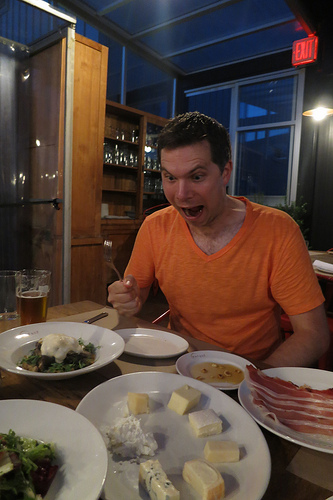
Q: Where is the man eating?
A: Restaurant.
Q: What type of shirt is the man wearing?
A: Tee.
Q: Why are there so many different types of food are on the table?
A: Variety.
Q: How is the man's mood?
A: Excited.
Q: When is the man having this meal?
A: In the evening.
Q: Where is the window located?
A: Behind the man.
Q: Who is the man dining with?
A: A friend.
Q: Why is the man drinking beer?
A: He likes it.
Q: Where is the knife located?
A: On table to the left of man.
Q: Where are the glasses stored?
A: On shelves in the rear left of the man.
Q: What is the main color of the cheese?
A: White.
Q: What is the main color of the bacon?
A: Red.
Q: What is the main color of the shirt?
A: Orange.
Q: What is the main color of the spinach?
A: Green.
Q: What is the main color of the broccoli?
A: Green.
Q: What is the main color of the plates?
A: White.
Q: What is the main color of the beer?
A: Brown.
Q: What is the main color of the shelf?
A: Brown.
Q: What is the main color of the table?
A: Brown.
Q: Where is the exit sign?
A: Back of man to right.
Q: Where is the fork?
A: In man's hand.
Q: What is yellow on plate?
A: Butter.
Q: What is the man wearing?
A: Orange shirt.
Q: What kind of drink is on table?
A: Beer.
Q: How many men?
A: 1.